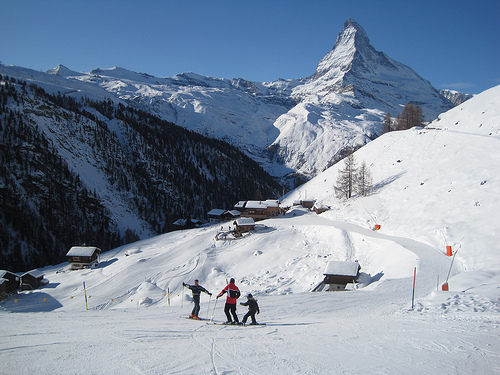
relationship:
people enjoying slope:
[2, 291, 499, 373] [176, 273, 268, 330]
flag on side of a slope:
[401, 265, 420, 314] [265, 130, 499, 367]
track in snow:
[238, 326, 286, 373] [1, 84, 498, 373]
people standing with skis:
[181, 278, 212, 320] [182, 311, 212, 328]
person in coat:
[215, 277, 241, 322] [211, 280, 243, 304]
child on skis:
[235, 292, 259, 329] [224, 322, 251, 330]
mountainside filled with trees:
[0, 0, 497, 310] [2, 72, 291, 272]